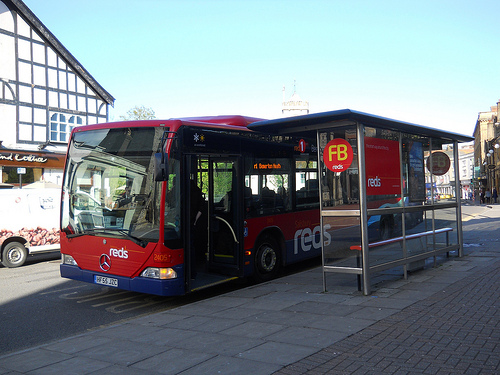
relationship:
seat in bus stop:
[344, 221, 456, 291] [237, 103, 481, 300]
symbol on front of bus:
[95, 251, 115, 275] [51, 111, 332, 308]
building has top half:
[0, 3, 126, 188] [0, 0, 117, 115]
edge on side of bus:
[183, 274, 242, 294] [51, 111, 332, 308]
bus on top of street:
[51, 111, 332, 308] [0, 250, 161, 361]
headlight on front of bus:
[136, 262, 181, 285] [51, 111, 332, 308]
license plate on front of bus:
[92, 272, 122, 291] [51, 111, 332, 308]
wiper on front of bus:
[63, 221, 152, 251] [51, 111, 332, 308]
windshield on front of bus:
[55, 125, 176, 245] [51, 111, 332, 308]